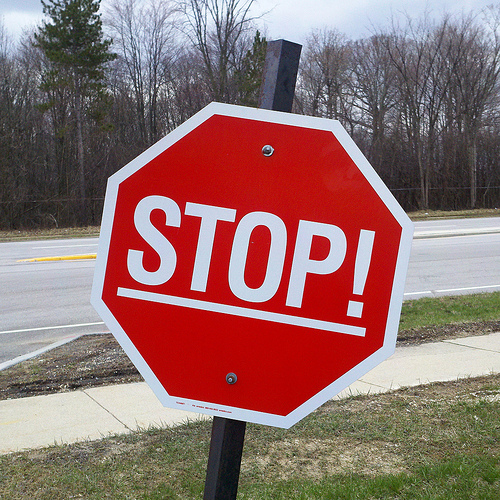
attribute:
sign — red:
[91, 99, 413, 429]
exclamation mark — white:
[347, 229, 378, 320]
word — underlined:
[126, 195, 348, 308]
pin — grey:
[226, 374, 237, 385]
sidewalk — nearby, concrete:
[2, 331, 500, 454]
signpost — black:
[203, 40, 304, 500]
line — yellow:
[19, 225, 498, 265]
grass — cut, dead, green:
[2, 290, 498, 499]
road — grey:
[1, 217, 500, 375]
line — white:
[115, 288, 366, 337]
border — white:
[89, 98, 417, 429]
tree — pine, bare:
[34, 1, 105, 214]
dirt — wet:
[3, 331, 145, 400]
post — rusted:
[258, 39, 303, 112]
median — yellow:
[17, 250, 99, 262]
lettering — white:
[128, 194, 347, 309]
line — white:
[0, 284, 499, 335]